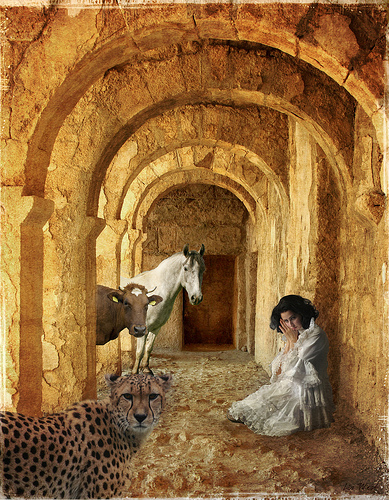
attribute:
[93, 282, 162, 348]
cow — brown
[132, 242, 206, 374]
horse — white, brown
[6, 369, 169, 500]
leopard — orange, black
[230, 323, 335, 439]
dress — white, lace, ruffled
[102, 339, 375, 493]
dirt — brown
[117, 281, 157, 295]
horns — curved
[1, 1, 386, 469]
sturcutre — old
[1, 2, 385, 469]
structure — stone, sand colored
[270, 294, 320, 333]
hair — black, brown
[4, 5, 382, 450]
arches — round